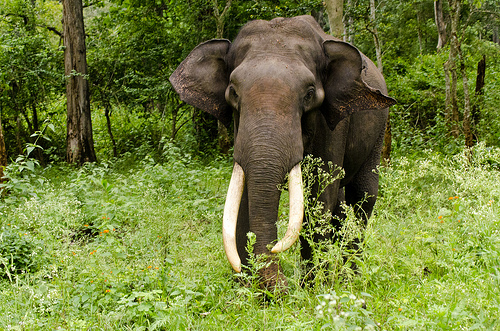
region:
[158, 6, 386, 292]
a large elephant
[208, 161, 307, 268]
two tusks on an elephant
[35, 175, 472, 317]
a brush filled area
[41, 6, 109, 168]
a tree trunk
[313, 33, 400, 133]
an elephant ear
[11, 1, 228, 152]
a wooded area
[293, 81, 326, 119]
the eye of an elephant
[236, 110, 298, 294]
an elephants trunk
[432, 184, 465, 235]
some small orange flowers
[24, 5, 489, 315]
a gray elephant in a grassy field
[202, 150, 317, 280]
two long white tusks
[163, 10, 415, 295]
elephant in tall grass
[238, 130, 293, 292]
trunk on elephant face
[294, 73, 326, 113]
eye on side of head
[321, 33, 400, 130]
flapping ear on elephant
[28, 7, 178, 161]
trees on edge of tall grass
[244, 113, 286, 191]
wrinkles on top of trunk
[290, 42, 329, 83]
sunken temples on head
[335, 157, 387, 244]
back leg of elephant leg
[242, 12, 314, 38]
bumpy top of elephant head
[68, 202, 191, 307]
orange flowers to the left of elephant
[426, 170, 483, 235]
orange flowers to the right of elephant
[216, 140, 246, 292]
left ivory tusk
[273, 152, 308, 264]
right ivory tusk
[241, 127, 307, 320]
elephants trunk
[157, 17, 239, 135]
elephant's left ear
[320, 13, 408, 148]
elephant's right ear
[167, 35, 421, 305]
large elephant with tusks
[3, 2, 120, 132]
tree trunk to the left of elephant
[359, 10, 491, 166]
tree trunks to the right of elephant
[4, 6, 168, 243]
Lush green forest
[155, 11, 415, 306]
Large gray bull elephant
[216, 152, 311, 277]
Two long ivory tusks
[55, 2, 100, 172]
Tall brown wood tree trunk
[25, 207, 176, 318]
Several small yellow wildflowers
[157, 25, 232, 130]
Large floppy gray elephant ear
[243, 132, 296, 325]
Strong efficient elephant trunk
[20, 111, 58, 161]
Green leaves at the top of a plant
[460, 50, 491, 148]
Broken dead rotted tree stump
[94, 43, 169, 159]
Thick jungle vines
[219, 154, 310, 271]
Two white elephant tusks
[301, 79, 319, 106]
Left eye of elephant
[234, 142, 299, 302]
Truck of an elephant reaching the ground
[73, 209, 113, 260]
Small orange flowers on a plant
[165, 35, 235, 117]
Right ear of elephant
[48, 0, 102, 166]
Bare tree trunk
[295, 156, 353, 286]
Plant growing as tall as elephant's trunk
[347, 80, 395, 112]
Brown spots on elephant's left ear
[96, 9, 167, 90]
Leaves on the trees in a jungle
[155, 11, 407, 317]
Elephant walking out of trees into grassy field